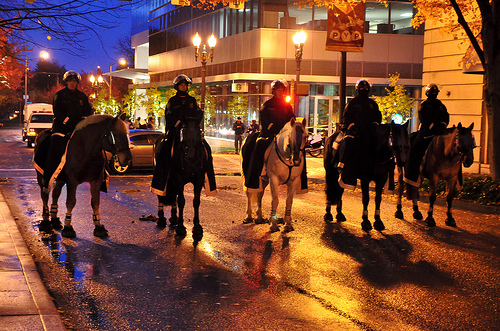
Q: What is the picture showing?
A: It is showing a road.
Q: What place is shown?
A: It is a road.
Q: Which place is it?
A: It is a road.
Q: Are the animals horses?
A: Yes, all the animals are horses.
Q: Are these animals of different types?
A: No, all the animals are horses.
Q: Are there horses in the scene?
A: Yes, there is a horse.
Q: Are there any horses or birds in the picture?
A: Yes, there is a horse.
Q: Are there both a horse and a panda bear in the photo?
A: No, there is a horse but no pandas.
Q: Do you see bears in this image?
A: No, there are no bears.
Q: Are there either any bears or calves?
A: No, there are no bears or calves.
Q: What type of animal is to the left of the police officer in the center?
A: The animal is a horse.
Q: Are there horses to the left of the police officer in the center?
A: Yes, there is a horse to the left of the police officer.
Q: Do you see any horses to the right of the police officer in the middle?
A: No, the horse is to the left of the policeman.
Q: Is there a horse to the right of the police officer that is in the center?
A: No, the horse is to the left of the policeman.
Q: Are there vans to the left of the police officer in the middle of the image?
A: No, there is a horse to the left of the police officer.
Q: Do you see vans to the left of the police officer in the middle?
A: No, there is a horse to the left of the police officer.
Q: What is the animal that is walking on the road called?
A: The animal is a horse.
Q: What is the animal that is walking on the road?
A: The animal is a horse.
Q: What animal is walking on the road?
A: The animal is a horse.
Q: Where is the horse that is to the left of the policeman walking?
A: The horse is walking on the road.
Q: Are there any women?
A: No, there are no women.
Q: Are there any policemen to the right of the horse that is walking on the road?
A: Yes, there is a policeman to the right of the horse.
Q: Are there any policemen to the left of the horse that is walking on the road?
A: No, the policeman is to the right of the horse.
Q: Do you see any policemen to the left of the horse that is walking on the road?
A: No, the policeman is to the right of the horse.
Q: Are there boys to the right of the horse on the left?
A: No, there is a policeman to the right of the horse.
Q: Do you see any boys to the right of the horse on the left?
A: No, there is a policeman to the right of the horse.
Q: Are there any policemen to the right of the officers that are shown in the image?
A: Yes, there is a policeman to the right of the officers.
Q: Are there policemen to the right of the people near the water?
A: Yes, there is a policeman to the right of the officers.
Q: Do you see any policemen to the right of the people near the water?
A: Yes, there is a policeman to the right of the officers.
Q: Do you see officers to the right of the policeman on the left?
A: Yes, there are officers to the right of the policeman.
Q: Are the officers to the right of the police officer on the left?
A: Yes, the officers are to the right of the policeman.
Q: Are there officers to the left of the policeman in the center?
A: Yes, there are officers to the left of the policeman.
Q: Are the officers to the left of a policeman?
A: Yes, the officers are to the left of a policeman.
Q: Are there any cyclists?
A: No, there are no cyclists.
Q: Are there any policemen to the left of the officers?
A: Yes, there is a policeman to the left of the officers.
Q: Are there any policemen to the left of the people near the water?
A: Yes, there is a policeman to the left of the officers.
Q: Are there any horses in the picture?
A: Yes, there is a horse.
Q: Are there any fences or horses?
A: Yes, there is a horse.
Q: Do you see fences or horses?
A: Yes, there is a horse.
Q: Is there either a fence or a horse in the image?
A: Yes, there is a horse.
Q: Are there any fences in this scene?
A: No, there are no fences.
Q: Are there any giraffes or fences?
A: No, there are no fences or giraffes.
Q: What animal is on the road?
A: The animal is a horse.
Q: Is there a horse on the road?
A: Yes, there is a horse on the road.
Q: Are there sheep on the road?
A: No, there is a horse on the road.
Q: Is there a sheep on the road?
A: No, there is a horse on the road.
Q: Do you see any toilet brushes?
A: No, there are no toilet brushes.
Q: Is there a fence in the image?
A: No, there are no fences.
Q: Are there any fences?
A: No, there are no fences.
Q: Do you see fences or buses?
A: No, there are no fences or buses.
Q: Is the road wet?
A: Yes, the road is wet.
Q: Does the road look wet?
A: Yes, the road is wet.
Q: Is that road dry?
A: No, the road is wet.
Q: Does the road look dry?
A: No, the road is wet.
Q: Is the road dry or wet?
A: The road is wet.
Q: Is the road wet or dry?
A: The road is wet.